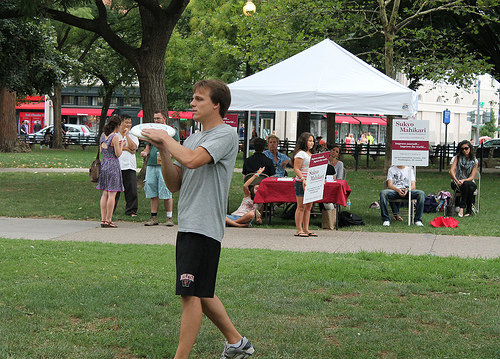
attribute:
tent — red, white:
[202, 31, 423, 134]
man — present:
[132, 77, 258, 350]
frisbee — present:
[131, 121, 178, 145]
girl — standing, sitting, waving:
[284, 124, 326, 239]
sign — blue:
[302, 150, 334, 225]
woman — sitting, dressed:
[447, 138, 482, 221]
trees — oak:
[4, 1, 499, 105]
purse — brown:
[95, 151, 100, 177]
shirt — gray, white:
[174, 118, 231, 244]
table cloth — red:
[251, 166, 343, 208]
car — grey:
[31, 119, 82, 146]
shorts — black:
[171, 226, 231, 300]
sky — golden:
[387, 17, 500, 125]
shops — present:
[17, 84, 199, 136]